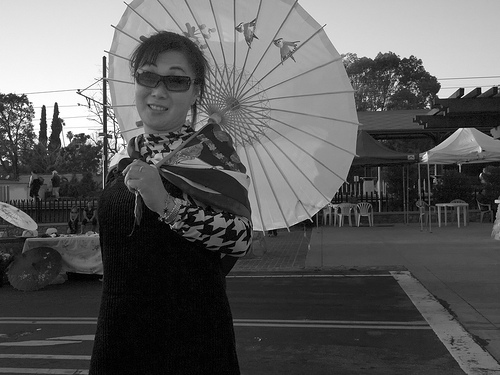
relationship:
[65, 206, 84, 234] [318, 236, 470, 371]
person on the side walk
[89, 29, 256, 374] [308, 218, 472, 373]
woman on the side walk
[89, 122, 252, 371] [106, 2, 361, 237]
woman holding umbrella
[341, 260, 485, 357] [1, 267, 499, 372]
paint on street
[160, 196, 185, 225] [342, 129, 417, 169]
bracelets under umbrella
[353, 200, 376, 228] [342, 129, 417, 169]
chair under umbrella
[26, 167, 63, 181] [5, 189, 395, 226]
face walking behind fence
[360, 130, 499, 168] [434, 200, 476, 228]
canopies above tables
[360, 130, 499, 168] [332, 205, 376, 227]
canopies above chairs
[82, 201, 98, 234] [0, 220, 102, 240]
person sitting on wall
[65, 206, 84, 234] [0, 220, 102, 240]
person sitting on wall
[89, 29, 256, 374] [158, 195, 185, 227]
woman wearing bracelets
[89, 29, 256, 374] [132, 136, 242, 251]
woman wearing shirt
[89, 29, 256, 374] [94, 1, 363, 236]
woman holding parasol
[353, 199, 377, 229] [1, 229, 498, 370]
chair on ground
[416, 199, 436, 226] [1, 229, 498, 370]
chair on ground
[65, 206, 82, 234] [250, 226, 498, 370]
person on sidewalk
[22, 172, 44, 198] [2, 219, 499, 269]
person on sidewalk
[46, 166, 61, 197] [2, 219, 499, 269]
person on sidewalk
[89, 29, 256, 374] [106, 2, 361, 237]
woman has umbrella